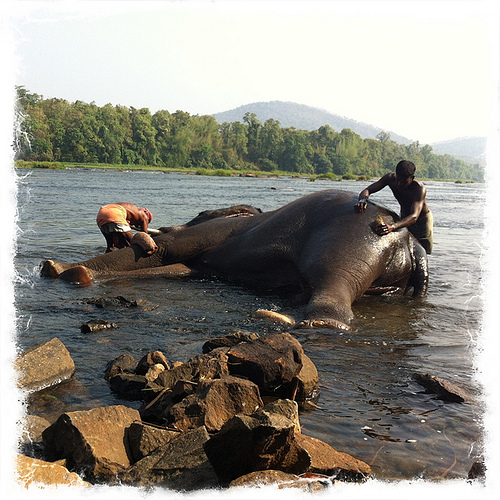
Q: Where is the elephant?
A: In the water.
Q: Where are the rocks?
A: In the water.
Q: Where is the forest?
A: On the other side of the water.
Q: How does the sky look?
A: Clear and blue.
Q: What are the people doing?
A: Bathing the elephant.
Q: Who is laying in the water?
A: The elephant.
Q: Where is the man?
A: Next to the elephant.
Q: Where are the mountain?
A: Behind the trees.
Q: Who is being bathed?
A: The elephant.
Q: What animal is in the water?
A: The elephant.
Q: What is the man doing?
A: Washing the elephant.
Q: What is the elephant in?
A: Water.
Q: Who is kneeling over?
A: The man.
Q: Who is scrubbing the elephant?
A: The man.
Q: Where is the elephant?
A: In water.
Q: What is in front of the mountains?
A: Trees.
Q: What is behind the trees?
A: Mountains.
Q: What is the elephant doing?
A: Laying in water.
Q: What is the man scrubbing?
A: The elephant's leg.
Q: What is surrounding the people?
A: Water.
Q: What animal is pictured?
A: An elephant.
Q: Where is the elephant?
A: In the water.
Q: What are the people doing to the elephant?
A: Washing it.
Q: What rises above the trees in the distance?
A: Mountain.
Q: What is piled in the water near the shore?
A: Rocks.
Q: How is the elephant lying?
A: On its side.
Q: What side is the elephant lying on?
A: The right.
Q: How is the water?
A: Calm.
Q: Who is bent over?
A: Person in front.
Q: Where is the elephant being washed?
A: In river.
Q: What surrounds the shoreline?
A: Trees.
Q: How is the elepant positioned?
A: Laying on side.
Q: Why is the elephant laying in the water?
A: To be washed.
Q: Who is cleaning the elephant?
A: Two men.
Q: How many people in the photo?
A: Two.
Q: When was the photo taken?
A: Day time.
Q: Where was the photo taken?
A: In water.